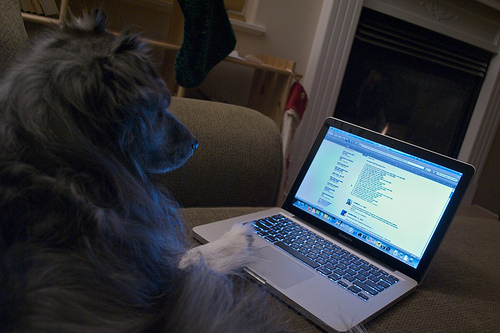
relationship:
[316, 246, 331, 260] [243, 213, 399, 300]
button on an keyboard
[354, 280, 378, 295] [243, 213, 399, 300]
button on keyboard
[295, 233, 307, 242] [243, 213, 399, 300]
button on a keyboard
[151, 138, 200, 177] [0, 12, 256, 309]
mouth on dog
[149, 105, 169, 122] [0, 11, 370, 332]
eye on dog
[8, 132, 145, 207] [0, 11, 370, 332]
neck on dog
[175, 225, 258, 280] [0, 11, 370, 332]
paw on dog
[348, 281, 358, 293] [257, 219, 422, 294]
button on keyboard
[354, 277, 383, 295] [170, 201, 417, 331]
button on keyboard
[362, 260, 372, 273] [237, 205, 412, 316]
keyboard button on keyboard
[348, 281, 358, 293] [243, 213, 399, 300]
button on keyboard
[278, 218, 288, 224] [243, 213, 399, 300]
button on keyboard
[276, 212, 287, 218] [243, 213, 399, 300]
button on keyboard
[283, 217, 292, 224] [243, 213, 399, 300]
button on keyboard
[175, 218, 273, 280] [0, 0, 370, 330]
paw of dog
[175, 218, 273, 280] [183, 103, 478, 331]
paw on laptop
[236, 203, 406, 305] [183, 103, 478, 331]
keyboard on laptop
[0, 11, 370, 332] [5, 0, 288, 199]
dog laying on couch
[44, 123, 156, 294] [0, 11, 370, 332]
fur of dog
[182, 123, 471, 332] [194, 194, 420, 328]
laptop on base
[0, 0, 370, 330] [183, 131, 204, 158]
dog has nose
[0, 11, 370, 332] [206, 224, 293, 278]
dog has leg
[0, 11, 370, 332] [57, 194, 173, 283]
dog has fur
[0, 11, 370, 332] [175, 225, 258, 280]
dog has paw